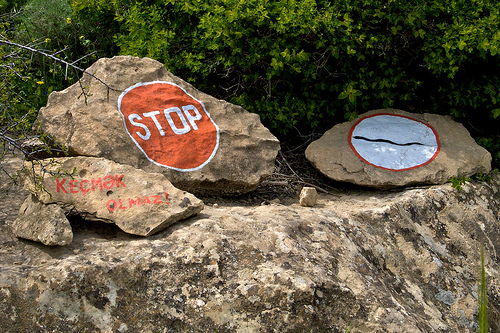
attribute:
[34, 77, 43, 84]
flower — yellow, wild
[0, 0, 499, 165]
woods — thick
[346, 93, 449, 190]
sign — painted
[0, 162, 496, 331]
rock — white, brown, grey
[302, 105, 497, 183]
rock — white, brown, grey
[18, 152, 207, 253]
rock — white, brown, grey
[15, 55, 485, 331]
rock — fossilized 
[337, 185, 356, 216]
ground — back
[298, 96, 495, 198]
rock — brown, tan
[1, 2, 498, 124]
bushes — leafy, green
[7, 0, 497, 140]
trees — leaf-covered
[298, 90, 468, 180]
sign — painted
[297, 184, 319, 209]
chip — small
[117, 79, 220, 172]
sign — red, white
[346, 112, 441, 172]
sign — red, white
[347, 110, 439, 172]
circle — red, white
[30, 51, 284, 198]
boulder — large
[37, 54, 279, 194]
rock — white, brown, grey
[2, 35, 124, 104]
branch — dead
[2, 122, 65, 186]
branch — dead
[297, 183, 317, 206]
stone — small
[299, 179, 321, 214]
rock — small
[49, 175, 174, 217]
writing — red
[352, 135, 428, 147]
snake — painted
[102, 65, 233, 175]
stop — red, white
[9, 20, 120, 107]
tree branch — dead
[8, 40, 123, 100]
branch — bare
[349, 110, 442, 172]
painting — black, white, red, circular 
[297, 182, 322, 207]
stone — tan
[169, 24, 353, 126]
branch — dried-up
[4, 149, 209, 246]
name — painted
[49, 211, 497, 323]
rock — large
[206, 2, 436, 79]
foliage — green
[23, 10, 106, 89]
flowers — yellow